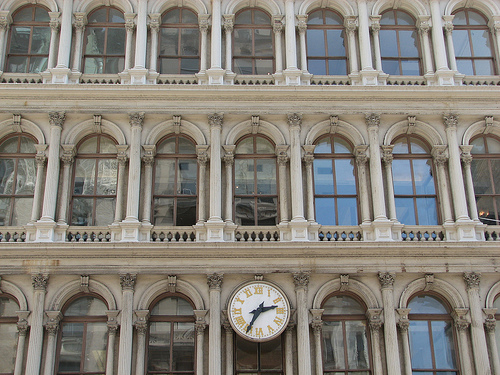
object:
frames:
[126, 258, 217, 369]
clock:
[225, 269, 307, 342]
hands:
[247, 296, 279, 332]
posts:
[120, 115, 393, 239]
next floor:
[114, 3, 381, 98]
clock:
[219, 281, 297, 344]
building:
[20, 25, 490, 374]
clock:
[230, 280, 297, 348]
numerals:
[229, 277, 291, 336]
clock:
[221, 276, 294, 349]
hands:
[238, 298, 283, 333]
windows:
[13, 105, 472, 235]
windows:
[27, 112, 497, 240]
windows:
[308, 115, 450, 233]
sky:
[311, 148, 360, 216]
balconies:
[22, 210, 496, 275]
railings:
[156, 195, 286, 248]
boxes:
[154, 52, 199, 78]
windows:
[153, 7, 204, 75]